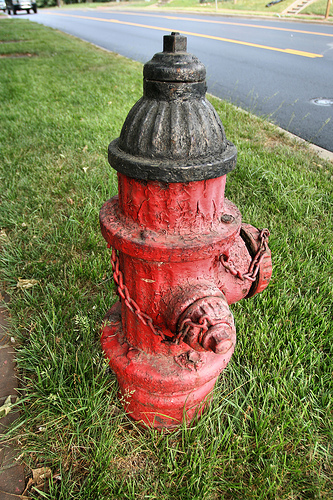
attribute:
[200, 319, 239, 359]
flange nut — red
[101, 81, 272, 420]
hydrant — sealed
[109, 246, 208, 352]
chain — red, rusted, painted, linked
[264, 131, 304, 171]
edge — grass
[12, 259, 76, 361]
leaves — brown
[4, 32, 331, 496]
grass — green, short, vibrant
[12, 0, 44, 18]
car — black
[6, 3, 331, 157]
street — black, asphalt, paved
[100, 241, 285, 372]
chain — red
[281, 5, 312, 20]
steps — grey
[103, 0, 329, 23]
hill — grassy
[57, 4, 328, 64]
lines — yellow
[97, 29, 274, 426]
fire hydrant — red, black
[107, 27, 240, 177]
top — black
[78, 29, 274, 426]
hydrant — paint repair-needing, black, red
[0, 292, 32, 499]
dirt — speckled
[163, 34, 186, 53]
nut — black, painted, square, metal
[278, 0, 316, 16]
steps — cement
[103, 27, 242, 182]
hydrant top — black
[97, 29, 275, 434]
hydrant — fire, red and black, red, old